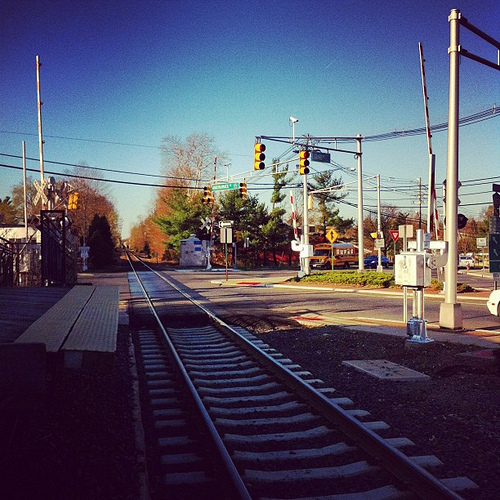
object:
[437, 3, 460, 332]
pole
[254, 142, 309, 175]
traffic lights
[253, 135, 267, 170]
trafficsignal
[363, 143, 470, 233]
ground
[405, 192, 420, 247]
ground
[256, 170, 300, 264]
tree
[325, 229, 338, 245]
sign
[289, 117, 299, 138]
trafficcamera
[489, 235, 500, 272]
street sign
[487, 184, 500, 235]
street sign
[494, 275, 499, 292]
pole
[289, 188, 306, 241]
crossing arm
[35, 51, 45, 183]
pole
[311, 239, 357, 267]
bus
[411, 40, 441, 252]
gate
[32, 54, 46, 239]
gate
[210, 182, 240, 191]
sign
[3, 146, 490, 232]
power line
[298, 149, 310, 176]
traffic signal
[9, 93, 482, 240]
lines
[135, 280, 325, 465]
tracks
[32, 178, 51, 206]
sign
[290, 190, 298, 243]
arm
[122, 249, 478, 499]
tracks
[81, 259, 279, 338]
road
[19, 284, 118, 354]
bench